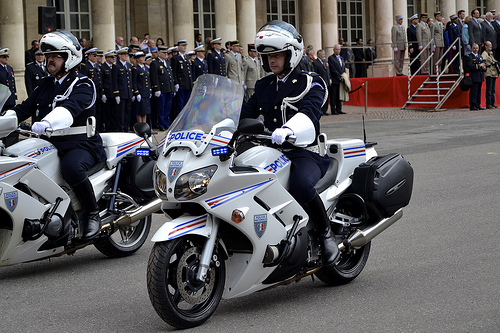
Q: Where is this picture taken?
A: Day time.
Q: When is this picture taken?
A: Parade.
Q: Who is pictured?
A: Police.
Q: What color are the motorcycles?
A: White.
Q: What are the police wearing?
A: Uniforms.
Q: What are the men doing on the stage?
A: Saluting.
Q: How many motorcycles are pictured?
A: 2.